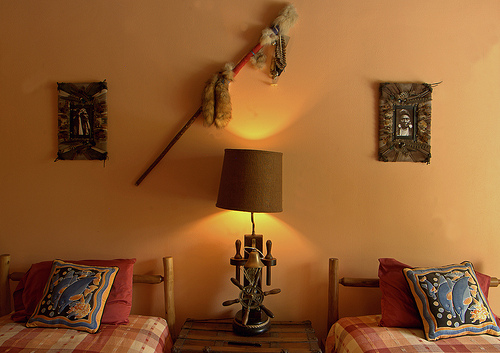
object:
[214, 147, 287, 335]
lamp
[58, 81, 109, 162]
photograph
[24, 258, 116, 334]
pillow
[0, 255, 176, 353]
bed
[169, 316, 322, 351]
end table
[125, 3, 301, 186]
weapon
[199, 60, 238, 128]
fur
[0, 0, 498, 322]
wall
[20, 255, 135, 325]
pillow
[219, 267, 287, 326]
wheel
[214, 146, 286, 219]
shade